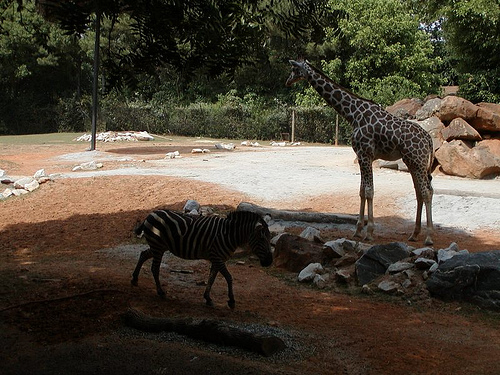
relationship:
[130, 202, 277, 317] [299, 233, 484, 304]
zebra by rocks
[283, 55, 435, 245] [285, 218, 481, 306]
giraffe next to rocks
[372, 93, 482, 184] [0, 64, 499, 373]
rocks in enclosure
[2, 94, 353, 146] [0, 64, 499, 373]
fence enclosing enclosure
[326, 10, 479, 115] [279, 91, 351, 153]
tree next to pin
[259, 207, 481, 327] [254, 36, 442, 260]
rocks next to giraffe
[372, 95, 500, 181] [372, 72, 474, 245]
rocks in enclosure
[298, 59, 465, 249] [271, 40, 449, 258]
side of giraffe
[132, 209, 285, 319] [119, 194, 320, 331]
side of zebra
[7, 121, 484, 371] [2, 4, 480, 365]
dirt of enclosure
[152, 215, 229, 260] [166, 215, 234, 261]
stripes on torso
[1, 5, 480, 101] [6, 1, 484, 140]
leaves on trees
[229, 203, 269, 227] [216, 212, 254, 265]
mane on neck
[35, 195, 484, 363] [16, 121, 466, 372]
shadow on ground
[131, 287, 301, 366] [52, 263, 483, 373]
log on surface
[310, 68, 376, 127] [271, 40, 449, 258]
neck on giraffe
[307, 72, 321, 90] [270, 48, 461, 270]
spots on giraffe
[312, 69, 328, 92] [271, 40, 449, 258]
spots on giraffe